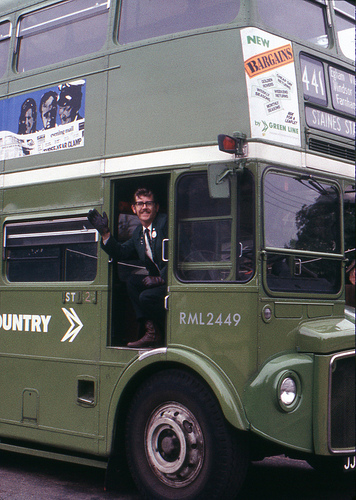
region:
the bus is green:
[0, 0, 354, 499]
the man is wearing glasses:
[85, 179, 195, 342]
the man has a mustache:
[113, 186, 170, 228]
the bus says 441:
[295, 48, 326, 104]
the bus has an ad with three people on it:
[2, 77, 86, 157]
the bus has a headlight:
[267, 364, 308, 419]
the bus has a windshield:
[257, 166, 346, 307]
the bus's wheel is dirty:
[124, 378, 231, 499]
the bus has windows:
[3, 156, 261, 297]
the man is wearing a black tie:
[121, 180, 182, 291]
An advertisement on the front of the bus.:
[232, 13, 304, 161]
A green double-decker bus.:
[11, 1, 344, 485]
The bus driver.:
[89, 181, 179, 347]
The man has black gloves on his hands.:
[78, 168, 173, 291]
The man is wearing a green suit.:
[90, 183, 195, 361]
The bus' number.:
[174, 298, 241, 339]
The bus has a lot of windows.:
[1, 157, 350, 300]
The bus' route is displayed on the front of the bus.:
[295, 43, 350, 138]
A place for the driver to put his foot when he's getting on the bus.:
[66, 369, 100, 412]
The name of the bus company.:
[0, 298, 92, 363]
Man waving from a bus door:
[85, 179, 169, 354]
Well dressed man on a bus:
[104, 166, 173, 348]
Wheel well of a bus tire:
[137, 397, 209, 492]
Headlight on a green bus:
[273, 360, 303, 415]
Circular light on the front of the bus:
[272, 366, 303, 413]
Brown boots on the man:
[122, 305, 164, 350]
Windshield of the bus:
[257, 161, 347, 306]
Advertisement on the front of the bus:
[238, 21, 307, 148]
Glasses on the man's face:
[131, 199, 155, 210]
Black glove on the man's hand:
[86, 205, 112, 236]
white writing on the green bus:
[176, 308, 241, 324]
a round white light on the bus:
[275, 370, 293, 403]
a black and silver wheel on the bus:
[119, 359, 225, 493]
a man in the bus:
[82, 180, 166, 344]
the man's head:
[125, 184, 156, 220]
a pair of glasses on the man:
[129, 195, 153, 204]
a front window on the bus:
[257, 162, 341, 292]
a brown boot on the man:
[123, 315, 159, 349]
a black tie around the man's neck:
[141, 226, 155, 253]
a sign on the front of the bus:
[238, 24, 302, 148]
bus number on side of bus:
[175, 302, 246, 327]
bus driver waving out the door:
[89, 172, 170, 353]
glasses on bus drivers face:
[132, 189, 162, 215]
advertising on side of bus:
[1, 79, 99, 155]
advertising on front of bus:
[235, 23, 302, 144]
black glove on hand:
[84, 199, 117, 250]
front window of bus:
[262, 165, 351, 295]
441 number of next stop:
[296, 50, 335, 105]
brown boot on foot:
[120, 309, 171, 352]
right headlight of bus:
[271, 363, 309, 434]